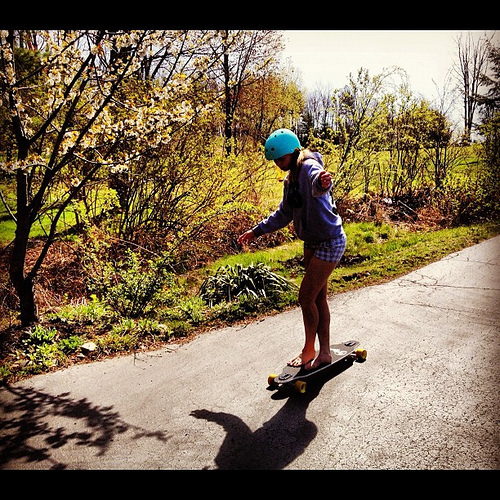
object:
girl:
[236, 126, 348, 369]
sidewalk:
[1, 230, 497, 470]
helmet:
[263, 129, 303, 158]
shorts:
[302, 234, 348, 263]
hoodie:
[252, 152, 345, 241]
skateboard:
[268, 339, 368, 394]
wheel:
[354, 345, 369, 362]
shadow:
[189, 385, 323, 471]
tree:
[1, 29, 224, 324]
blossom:
[73, 177, 82, 190]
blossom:
[109, 164, 129, 174]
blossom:
[157, 134, 171, 144]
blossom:
[173, 101, 193, 125]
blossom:
[135, 117, 157, 134]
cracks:
[396, 271, 500, 298]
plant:
[197, 261, 301, 305]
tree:
[454, 31, 496, 140]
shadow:
[1, 380, 174, 470]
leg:
[306, 241, 333, 368]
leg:
[288, 237, 347, 370]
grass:
[41, 221, 498, 328]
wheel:
[294, 378, 309, 397]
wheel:
[267, 373, 278, 386]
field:
[1, 146, 499, 385]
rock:
[79, 342, 99, 356]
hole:
[269, 146, 275, 153]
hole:
[263, 147, 270, 154]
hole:
[281, 130, 286, 132]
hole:
[272, 134, 277, 139]